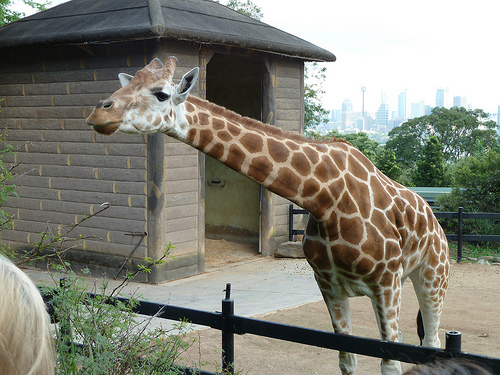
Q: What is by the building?
A: Curious giraffe.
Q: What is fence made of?
A: Metal.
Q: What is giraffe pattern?
A: Spotted.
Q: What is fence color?
A: Black.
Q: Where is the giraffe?
A: Zoo.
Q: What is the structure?
A: Stone.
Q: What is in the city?
A: Skyscrapers.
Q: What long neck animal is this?
A: A giraffe.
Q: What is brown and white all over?
A: The giraffe.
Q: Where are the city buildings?
A: In the far distance.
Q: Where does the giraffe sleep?
A: Inside the little house.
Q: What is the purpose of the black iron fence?
A: To enclose the giraffe.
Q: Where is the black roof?
A: On top of the hut.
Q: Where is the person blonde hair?
A: In the corner of the picture.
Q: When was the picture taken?
A: Daytime.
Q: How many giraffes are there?
A: One.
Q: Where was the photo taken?
A: At a zoo.